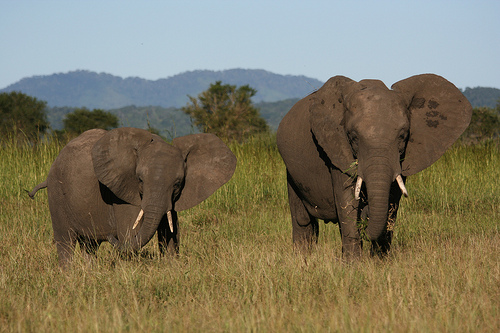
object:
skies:
[0, 0, 499, 92]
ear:
[309, 75, 358, 177]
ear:
[173, 133, 237, 210]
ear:
[92, 124, 144, 208]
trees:
[0, 88, 56, 144]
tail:
[22, 179, 48, 200]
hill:
[0, 68, 499, 146]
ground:
[0, 107, 499, 333]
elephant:
[275, 71, 472, 263]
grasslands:
[1, 91, 500, 332]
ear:
[391, 72, 473, 175]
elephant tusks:
[131, 207, 174, 234]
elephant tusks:
[353, 173, 410, 199]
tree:
[180, 78, 270, 142]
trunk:
[356, 148, 400, 241]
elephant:
[21, 124, 239, 265]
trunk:
[127, 186, 172, 256]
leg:
[49, 201, 78, 267]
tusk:
[353, 176, 363, 201]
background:
[0, 0, 499, 333]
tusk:
[132, 209, 145, 229]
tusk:
[166, 209, 174, 232]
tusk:
[394, 173, 409, 198]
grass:
[1, 130, 500, 332]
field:
[2, 68, 500, 332]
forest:
[0, 68, 499, 154]